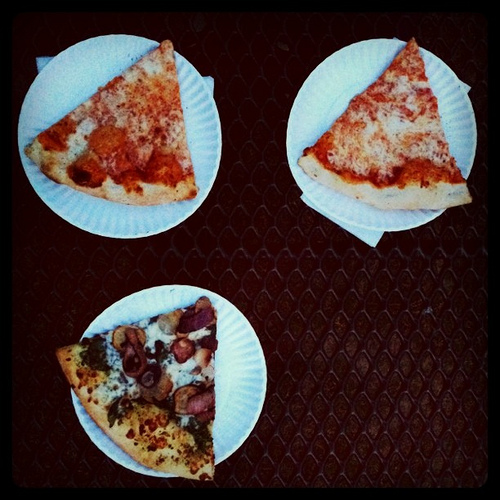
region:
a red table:
[278, 253, 482, 498]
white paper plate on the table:
[55, 275, 273, 484]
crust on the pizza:
[58, 344, 216, 494]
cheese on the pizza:
[173, 367, 192, 387]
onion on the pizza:
[181, 310, 214, 336]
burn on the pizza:
[65, 167, 97, 187]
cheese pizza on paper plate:
[279, 33, 473, 246]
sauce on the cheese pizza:
[376, 168, 407, 182]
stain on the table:
[188, 8, 212, 30]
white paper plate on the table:
[19, 36, 231, 252]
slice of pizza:
[56, 294, 217, 489]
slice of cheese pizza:
[22, 38, 198, 206]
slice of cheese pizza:
[298, 37, 472, 209]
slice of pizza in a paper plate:
[56, 282, 264, 479]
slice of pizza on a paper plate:
[15, 31, 220, 232]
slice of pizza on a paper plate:
[280, 35, 475, 230]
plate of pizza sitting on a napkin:
[281, 36, 476, 243]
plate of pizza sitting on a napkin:
[15, 30, 216, 235]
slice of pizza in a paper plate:
[285, 35, 475, 230]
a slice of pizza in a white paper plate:
[16, 34, 222, 239]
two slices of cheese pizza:
[25, 32, 475, 240]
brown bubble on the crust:
[70, 165, 101, 185]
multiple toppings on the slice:
[50, 296, 215, 476]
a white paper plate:
[15, 31, 220, 236]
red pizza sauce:
[385, 156, 460, 181]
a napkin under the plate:
[295, 195, 380, 245]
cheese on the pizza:
[60, 115, 95, 150]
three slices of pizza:
[17, 32, 479, 479]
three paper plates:
[17, 35, 478, 476]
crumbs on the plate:
[126, 51, 140, 62]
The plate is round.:
[15, 25, 230, 247]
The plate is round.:
[285, 15, 487, 256]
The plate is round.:
[44, 272, 278, 493]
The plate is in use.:
[49, 267, 273, 492]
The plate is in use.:
[9, 15, 230, 257]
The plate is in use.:
[271, 4, 485, 262]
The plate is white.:
[39, 273, 279, 495]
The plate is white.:
[8, 20, 228, 253]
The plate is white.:
[268, 22, 492, 255]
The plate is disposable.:
[39, 272, 281, 488]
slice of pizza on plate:
[25, 36, 205, 209]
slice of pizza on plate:
[301, 39, 478, 212]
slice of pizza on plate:
[49, 295, 250, 482]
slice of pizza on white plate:
[34, 41, 201, 202]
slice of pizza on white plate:
[299, 31, 476, 211]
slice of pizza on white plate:
[56, 292, 219, 480]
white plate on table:
[56, 282, 283, 482]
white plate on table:
[19, 34, 228, 241]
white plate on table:
[283, 34, 474, 232]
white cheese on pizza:
[91, 305, 230, 437]